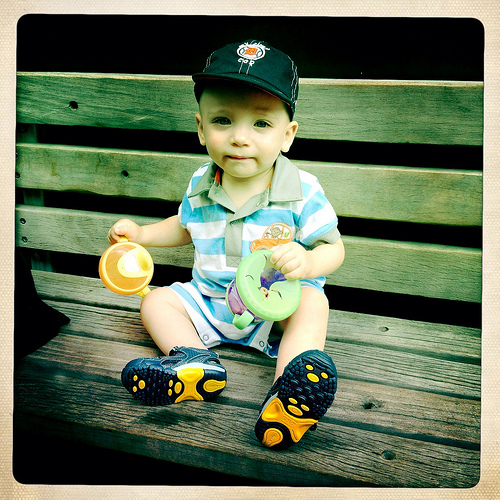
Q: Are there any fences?
A: No, there are no fences.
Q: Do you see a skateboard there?
A: No, there are no skateboards.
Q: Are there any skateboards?
A: No, there are no skateboards.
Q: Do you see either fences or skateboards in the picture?
A: No, there are no skateboards or fences.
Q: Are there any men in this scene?
A: No, there are no men.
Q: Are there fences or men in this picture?
A: No, there are no men or fences.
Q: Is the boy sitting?
A: Yes, the boy is sitting.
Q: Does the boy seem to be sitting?
A: Yes, the boy is sitting.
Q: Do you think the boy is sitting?
A: Yes, the boy is sitting.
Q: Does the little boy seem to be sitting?
A: Yes, the boy is sitting.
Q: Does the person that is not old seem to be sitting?
A: Yes, the boy is sitting.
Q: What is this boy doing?
A: The boy is sitting.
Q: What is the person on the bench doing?
A: The boy is sitting.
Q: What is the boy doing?
A: The boy is sitting.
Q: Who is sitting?
A: The boy is sitting.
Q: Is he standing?
A: No, the boy is sitting.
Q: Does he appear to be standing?
A: No, the boy is sitting.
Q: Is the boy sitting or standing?
A: The boy is sitting.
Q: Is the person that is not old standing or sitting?
A: The boy is sitting.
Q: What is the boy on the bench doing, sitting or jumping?
A: The boy is sitting.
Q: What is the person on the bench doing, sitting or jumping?
A: The boy is sitting.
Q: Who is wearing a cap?
A: The boy is wearing a cap.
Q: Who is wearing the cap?
A: The boy is wearing a cap.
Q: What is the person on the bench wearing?
A: The boy is wearing a cap.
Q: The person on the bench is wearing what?
A: The boy is wearing a cap.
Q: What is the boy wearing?
A: The boy is wearing a cap.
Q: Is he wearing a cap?
A: Yes, the boy is wearing a cap.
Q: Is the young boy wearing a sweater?
A: No, the boy is wearing a cap.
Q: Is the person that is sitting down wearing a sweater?
A: No, the boy is wearing a cap.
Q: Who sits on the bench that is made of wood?
A: The boy sits on the bench.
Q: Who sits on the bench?
A: The boy sits on the bench.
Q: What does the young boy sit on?
A: The boy sits on the bench.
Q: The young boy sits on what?
A: The boy sits on the bench.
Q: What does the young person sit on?
A: The boy sits on the bench.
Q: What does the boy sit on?
A: The boy sits on the bench.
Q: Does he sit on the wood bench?
A: Yes, the boy sits on the bench.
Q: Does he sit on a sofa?
A: No, the boy sits on the bench.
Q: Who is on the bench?
A: The boy is on the bench.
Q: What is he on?
A: The boy is on the bench.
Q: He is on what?
A: The boy is on the bench.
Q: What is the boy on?
A: The boy is on the bench.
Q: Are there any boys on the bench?
A: Yes, there is a boy on the bench.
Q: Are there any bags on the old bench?
A: No, there is a boy on the bench.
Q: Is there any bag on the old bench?
A: No, there is a boy on the bench.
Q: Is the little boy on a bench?
A: Yes, the boy is on a bench.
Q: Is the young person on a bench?
A: Yes, the boy is on a bench.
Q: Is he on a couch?
A: No, the boy is on a bench.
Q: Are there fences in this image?
A: No, there are no fences.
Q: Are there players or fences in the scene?
A: No, there are no fences or players.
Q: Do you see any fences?
A: No, there are no fences.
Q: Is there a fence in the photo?
A: No, there are no fences.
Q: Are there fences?
A: No, there are no fences.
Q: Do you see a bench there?
A: Yes, there is a bench.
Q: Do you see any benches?
A: Yes, there is a bench.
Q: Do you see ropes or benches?
A: Yes, there is a bench.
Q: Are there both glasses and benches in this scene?
A: No, there is a bench but no glasses.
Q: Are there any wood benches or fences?
A: Yes, there is a wood bench.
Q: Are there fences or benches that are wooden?
A: Yes, the bench is wooden.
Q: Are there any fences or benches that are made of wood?
A: Yes, the bench is made of wood.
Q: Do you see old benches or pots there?
A: Yes, there is an old bench.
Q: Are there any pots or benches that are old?
A: Yes, the bench is old.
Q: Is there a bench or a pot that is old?
A: Yes, the bench is old.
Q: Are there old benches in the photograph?
A: Yes, there is an old bench.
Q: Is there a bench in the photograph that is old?
A: Yes, there is a bench that is old.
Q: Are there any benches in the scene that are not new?
A: Yes, there is a old bench.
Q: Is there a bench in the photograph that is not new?
A: Yes, there is a old bench.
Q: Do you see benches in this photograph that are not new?
A: Yes, there is a old bench.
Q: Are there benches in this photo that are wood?
A: Yes, there is a wood bench.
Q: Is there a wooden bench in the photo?
A: Yes, there is a wood bench.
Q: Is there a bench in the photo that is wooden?
A: Yes, there is a bench that is wooden.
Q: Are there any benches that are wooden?
A: Yes, there is a bench that is wooden.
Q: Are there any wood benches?
A: Yes, there is a bench that is made of wood.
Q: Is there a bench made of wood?
A: Yes, there is a bench that is made of wood.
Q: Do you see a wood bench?
A: Yes, there is a bench that is made of wood.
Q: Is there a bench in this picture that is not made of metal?
A: Yes, there is a bench that is made of wood.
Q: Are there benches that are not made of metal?
A: Yes, there is a bench that is made of wood.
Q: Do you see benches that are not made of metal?
A: Yes, there is a bench that is made of wood.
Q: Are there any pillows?
A: No, there are no pillows.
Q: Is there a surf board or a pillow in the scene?
A: No, there are no pillows or surfboards.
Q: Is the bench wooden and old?
A: Yes, the bench is wooden and old.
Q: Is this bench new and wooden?
A: No, the bench is wooden but old.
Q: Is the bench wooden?
A: Yes, the bench is wooden.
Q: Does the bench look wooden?
A: Yes, the bench is wooden.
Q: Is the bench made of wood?
A: Yes, the bench is made of wood.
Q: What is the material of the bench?
A: The bench is made of wood.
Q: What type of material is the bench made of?
A: The bench is made of wood.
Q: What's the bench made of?
A: The bench is made of wood.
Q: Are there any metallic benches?
A: No, there is a bench but it is wooden.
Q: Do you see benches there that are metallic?
A: No, there is a bench but it is wooden.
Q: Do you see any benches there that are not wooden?
A: No, there is a bench but it is wooden.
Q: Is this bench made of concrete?
A: No, the bench is made of wood.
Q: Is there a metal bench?
A: No, there is a bench but it is made of wood.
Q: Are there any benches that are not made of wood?
A: No, there is a bench but it is made of wood.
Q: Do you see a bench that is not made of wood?
A: No, there is a bench but it is made of wood.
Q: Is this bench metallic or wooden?
A: The bench is wooden.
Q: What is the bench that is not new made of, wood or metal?
A: The bench is made of wood.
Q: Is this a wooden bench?
A: Yes, this is a wooden bench.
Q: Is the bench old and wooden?
A: Yes, the bench is old and wooden.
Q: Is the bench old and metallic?
A: No, the bench is old but wooden.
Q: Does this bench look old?
A: Yes, the bench is old.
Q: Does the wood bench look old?
A: Yes, the bench is old.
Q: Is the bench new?
A: No, the bench is old.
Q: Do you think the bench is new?
A: No, the bench is old.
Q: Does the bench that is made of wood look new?
A: No, the bench is old.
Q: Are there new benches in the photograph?
A: No, there is a bench but it is old.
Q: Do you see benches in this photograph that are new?
A: No, there is a bench but it is old.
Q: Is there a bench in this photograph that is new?
A: No, there is a bench but it is old.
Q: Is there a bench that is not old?
A: No, there is a bench but it is old.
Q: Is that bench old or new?
A: The bench is old.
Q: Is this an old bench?
A: Yes, this is an old bench.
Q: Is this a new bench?
A: No, this is an old bench.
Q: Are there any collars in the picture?
A: Yes, there is a collar.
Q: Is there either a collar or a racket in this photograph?
A: Yes, there is a collar.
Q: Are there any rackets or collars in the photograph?
A: Yes, there is a collar.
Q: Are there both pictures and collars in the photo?
A: No, there is a collar but no pictures.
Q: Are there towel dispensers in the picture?
A: No, there are no towel dispensers.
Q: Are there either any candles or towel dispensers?
A: No, there are no towel dispensers or candles.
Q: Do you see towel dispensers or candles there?
A: No, there are no towel dispensers or candles.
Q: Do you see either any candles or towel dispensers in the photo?
A: No, there are no towel dispensers or candles.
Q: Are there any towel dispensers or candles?
A: No, there are no towel dispensers or candles.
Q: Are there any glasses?
A: No, there are no glasses.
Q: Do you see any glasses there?
A: No, there are no glasses.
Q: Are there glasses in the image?
A: No, there are no glasses.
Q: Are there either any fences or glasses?
A: No, there are no glasses or fences.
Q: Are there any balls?
A: No, there are no balls.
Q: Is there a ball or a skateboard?
A: No, there are no balls or skateboards.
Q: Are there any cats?
A: No, there are no cats.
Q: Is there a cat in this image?
A: No, there are no cats.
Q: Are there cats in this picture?
A: No, there are no cats.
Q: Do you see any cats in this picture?
A: No, there are no cats.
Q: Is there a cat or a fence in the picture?
A: No, there are no cats or fences.